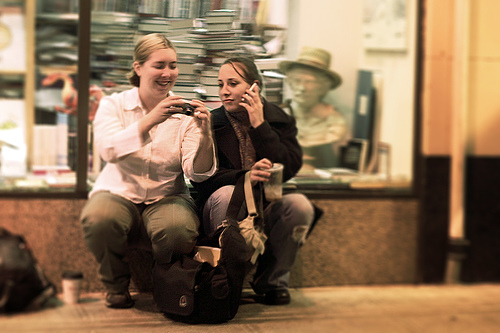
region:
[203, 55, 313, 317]
A woman squatting while on a cell phone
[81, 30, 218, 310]
A woman squatting while holding a digital camera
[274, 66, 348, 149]
A bust of a male figure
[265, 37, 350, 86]
A hat resting on top of a statue bust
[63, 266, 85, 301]
A coffee cup with a lback lid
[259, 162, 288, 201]
A plastic cup with a black straw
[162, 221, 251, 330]
A black shoulder bag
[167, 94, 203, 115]
A silver digital camera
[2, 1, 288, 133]
Multiple Stacks of books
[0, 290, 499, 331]
The city sidewalk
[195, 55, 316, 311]
woman talking on cell phone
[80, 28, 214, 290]
woman looking at cell phone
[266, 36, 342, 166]
mannequin head in window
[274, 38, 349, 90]
beige striped hat on mannequin head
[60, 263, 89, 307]
styrofoam coffee cup on ground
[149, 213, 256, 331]
black hobo style bag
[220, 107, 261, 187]
knit scarf of neck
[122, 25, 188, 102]
blonde hair in a bun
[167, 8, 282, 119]
books in display window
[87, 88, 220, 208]
white button down shirt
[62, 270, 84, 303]
a black and white coffee cup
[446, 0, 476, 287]
a long white pole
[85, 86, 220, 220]
a woman's white shirt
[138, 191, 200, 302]
the leg of a woman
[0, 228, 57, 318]
part of a black bag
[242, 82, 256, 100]
a gray cellphone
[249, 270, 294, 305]
the shoe of a woman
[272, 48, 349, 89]
a large hat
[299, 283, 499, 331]
part of a concrete sidewalk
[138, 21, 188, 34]
a large book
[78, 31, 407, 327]
the women are looking a the camera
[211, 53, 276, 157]
a woman holding a phone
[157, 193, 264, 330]
bag on the ground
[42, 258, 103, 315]
cup with black lid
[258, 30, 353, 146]
statue wearing a hat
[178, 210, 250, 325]
the bag is black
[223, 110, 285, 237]
woman is holding an empty cup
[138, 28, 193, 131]
the woman is smiling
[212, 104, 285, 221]
the jacket is black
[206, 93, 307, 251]
woman is wearing a scarf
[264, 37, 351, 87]
brown hat on statue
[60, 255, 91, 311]
coffee cup sitting on ground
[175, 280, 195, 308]
design on side of purse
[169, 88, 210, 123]
small silver camera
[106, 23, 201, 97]
woman with blonde hair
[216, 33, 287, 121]
woman talking on cell phone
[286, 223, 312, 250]
hole in knee of jeans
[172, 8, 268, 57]
stack of books in building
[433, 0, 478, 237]
white pipe on side of building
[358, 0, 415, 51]
painting hanging on wall